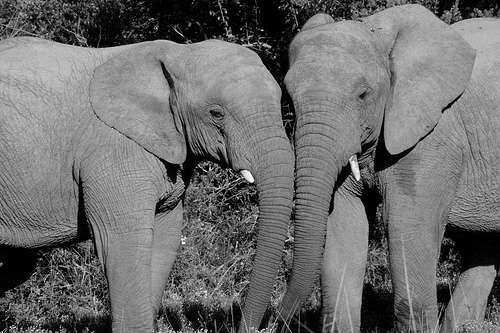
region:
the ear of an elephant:
[381, 2, 478, 158]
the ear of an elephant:
[84, 41, 186, 171]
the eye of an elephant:
[204, 101, 229, 122]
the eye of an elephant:
[354, 80, 373, 107]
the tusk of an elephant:
[345, 150, 367, 184]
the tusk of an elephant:
[236, 165, 260, 187]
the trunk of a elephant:
[286, 115, 338, 330]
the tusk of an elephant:
[236, 162, 294, 332]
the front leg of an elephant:
[84, 168, 160, 331]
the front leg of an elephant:
[379, 177, 444, 328]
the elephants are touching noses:
[214, 140, 344, 330]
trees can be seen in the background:
[13, 9, 485, 89]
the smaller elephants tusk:
[227, 161, 257, 187]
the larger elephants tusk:
[345, 148, 367, 190]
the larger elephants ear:
[364, 13, 473, 155]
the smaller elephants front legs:
[76, 163, 183, 329]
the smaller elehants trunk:
[226, 127, 298, 332]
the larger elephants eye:
[341, 73, 378, 112]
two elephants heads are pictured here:
[93, 8, 492, 183]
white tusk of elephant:
[236, 156, 262, 192]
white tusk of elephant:
[335, 147, 363, 182]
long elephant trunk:
[240, 100, 280, 330]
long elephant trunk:
[286, 87, 328, 318]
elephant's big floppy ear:
[379, 14, 470, 158]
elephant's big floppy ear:
[102, 54, 196, 164]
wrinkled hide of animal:
[0, 157, 61, 241]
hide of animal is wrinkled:
[451, 160, 499, 239]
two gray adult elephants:
[2, 16, 497, 297]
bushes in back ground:
[190, 201, 252, 269]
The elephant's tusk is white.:
[236, 163, 252, 188]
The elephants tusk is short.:
[241, 168, 252, 188]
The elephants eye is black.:
[210, 106, 222, 120]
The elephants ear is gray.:
[84, 46, 172, 161]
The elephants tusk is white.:
[351, 151, 358, 184]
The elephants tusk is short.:
[347, 156, 362, 183]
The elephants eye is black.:
[355, 84, 369, 103]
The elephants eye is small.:
[356, 84, 371, 105]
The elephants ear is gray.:
[383, 8, 475, 163]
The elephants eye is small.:
[207, 103, 224, 123]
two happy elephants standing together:
[3, 18, 499, 330]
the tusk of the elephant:
[337, 154, 362, 180]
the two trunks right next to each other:
[242, 140, 334, 331]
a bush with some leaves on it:
[198, 182, 247, 288]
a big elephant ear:
[379, 5, 473, 162]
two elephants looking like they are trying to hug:
[175, 18, 385, 331]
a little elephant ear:
[89, 46, 198, 172]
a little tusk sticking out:
[233, 165, 255, 183]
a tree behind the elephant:
[3, 0, 125, 37]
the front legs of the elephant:
[91, 228, 167, 331]